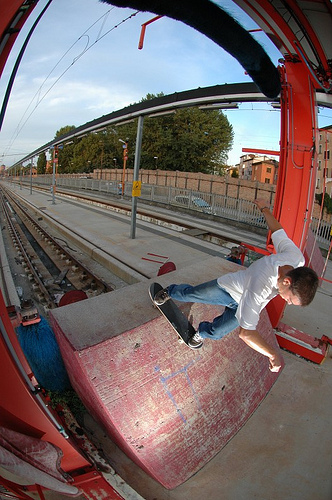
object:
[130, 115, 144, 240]
post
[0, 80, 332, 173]
rail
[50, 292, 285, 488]
ramp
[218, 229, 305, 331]
shirt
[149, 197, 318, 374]
boy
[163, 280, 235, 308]
jean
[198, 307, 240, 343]
jean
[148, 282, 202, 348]
skateboard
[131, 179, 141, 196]
sign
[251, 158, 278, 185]
building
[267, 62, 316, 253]
post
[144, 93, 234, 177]
tree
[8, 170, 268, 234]
fence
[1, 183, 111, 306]
tracks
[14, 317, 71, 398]
brush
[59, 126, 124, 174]
tree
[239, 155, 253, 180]
building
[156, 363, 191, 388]
mark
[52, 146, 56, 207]
pole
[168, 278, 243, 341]
jeans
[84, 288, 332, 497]
floor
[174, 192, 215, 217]
car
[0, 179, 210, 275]
walkway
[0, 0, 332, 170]
sky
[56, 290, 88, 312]
block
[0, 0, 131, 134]
wires